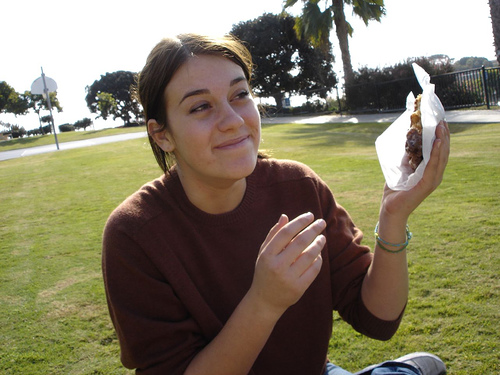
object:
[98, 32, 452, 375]
girl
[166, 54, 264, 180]
face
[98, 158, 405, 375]
sweater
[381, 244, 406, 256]
bracelet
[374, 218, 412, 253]
bracelet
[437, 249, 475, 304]
grass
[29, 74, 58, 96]
hoop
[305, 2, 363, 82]
palm tree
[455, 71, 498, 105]
fence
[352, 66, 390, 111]
tree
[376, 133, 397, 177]
wrapper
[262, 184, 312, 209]
shirt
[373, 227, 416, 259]
bracelets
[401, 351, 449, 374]
shoe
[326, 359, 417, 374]
jeans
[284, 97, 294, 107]
sign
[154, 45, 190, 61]
hair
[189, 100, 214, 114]
eyes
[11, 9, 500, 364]
park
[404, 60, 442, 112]
paper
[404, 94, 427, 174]
hotdog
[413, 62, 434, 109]
wax paper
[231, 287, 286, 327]
wrist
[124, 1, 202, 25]
sky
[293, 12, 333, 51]
leaves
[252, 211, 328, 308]
hand